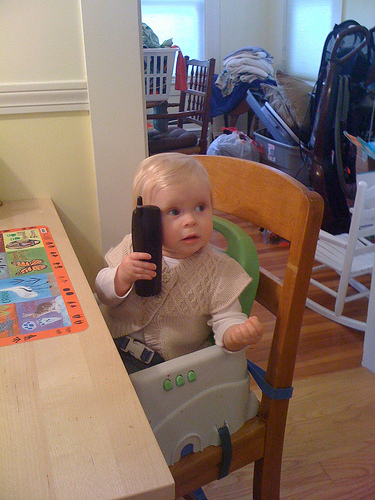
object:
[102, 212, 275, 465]
seat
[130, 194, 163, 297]
phone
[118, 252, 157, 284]
hand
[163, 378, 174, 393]
buttons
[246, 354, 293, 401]
strap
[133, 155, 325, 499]
chair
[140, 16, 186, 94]
laundry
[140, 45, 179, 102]
basket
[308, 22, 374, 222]
vacuum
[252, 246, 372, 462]
floor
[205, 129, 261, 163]
bag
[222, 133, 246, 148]
ties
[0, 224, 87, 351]
mat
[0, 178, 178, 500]
table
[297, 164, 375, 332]
chair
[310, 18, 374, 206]
pen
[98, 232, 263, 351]
shirt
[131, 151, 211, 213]
hair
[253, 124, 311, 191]
container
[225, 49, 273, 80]
clothes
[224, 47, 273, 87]
pile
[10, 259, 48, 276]
butterfly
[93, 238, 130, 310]
arm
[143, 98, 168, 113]
table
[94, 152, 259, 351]
baby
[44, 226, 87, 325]
border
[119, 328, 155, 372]
buckle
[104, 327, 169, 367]
waist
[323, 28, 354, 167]
rail